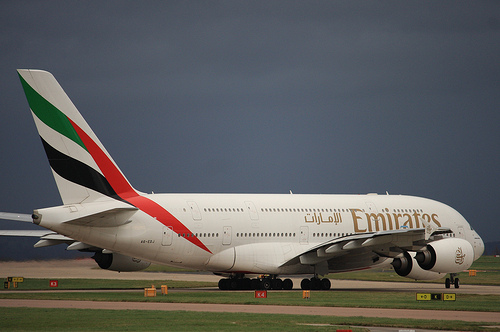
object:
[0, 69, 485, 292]
plane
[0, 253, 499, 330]
runway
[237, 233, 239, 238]
window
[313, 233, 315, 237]
window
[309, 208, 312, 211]
window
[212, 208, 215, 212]
window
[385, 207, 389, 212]
window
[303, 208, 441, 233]
words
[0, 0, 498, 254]
sky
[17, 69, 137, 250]
tail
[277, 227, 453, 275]
wing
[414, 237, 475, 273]
engine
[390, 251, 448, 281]
engine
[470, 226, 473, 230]
window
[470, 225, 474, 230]
cockpit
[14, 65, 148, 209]
stabilizer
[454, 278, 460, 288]
wheel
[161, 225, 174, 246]
door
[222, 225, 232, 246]
door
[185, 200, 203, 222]
door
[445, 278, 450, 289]
wheel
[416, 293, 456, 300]
sign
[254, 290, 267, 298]
sign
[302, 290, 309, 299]
sign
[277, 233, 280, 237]
window